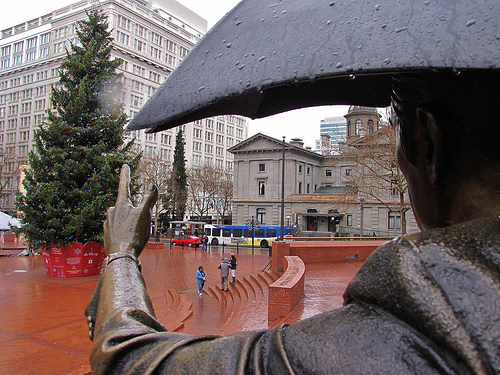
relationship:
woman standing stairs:
[226, 250, 238, 285] [200, 263, 282, 314]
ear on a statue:
[414, 103, 446, 192] [97, 84, 496, 372]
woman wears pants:
[195, 265, 206, 297] [197, 283, 205, 293]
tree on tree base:
[9, 3, 140, 252] [35, 239, 106, 279]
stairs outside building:
[206, 269, 283, 331] [224, 106, 413, 242]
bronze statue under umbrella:
[109, 100, 499, 350] [84, 9, 499, 161]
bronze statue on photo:
[85, 0, 500, 374] [6, 4, 495, 374]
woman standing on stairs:
[195, 265, 206, 297] [190, 257, 290, 307]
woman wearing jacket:
[195, 265, 206, 297] [191, 269, 208, 285]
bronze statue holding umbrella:
[85, 0, 500, 374] [146, 10, 483, 110]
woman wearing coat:
[195, 265, 206, 297] [223, 256, 239, 281]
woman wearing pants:
[195, 265, 206, 297] [223, 264, 236, 294]